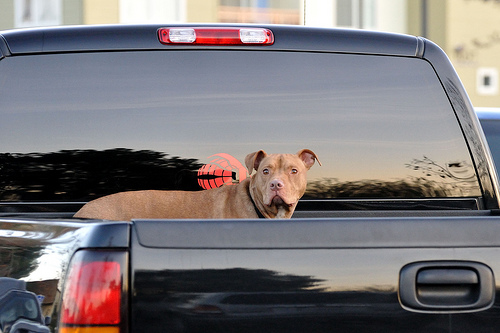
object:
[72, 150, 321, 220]
dog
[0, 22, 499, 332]
car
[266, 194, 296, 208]
mouth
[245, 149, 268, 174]
ear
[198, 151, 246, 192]
sticker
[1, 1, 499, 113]
buildings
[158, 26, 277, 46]
lights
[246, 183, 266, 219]
collar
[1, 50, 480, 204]
window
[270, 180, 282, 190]
nose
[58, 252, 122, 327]
light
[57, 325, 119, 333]
light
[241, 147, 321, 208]
head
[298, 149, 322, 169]
ear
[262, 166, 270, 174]
eye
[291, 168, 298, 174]
eye